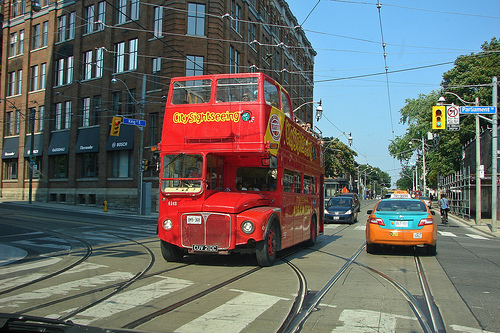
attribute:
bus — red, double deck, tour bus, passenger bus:
[158, 69, 326, 262]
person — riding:
[439, 193, 450, 226]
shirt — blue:
[439, 196, 449, 210]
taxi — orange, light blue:
[366, 198, 437, 252]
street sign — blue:
[459, 105, 497, 115]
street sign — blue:
[120, 115, 149, 129]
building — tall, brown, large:
[1, 1, 159, 214]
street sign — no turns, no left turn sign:
[447, 106, 461, 128]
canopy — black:
[48, 130, 71, 156]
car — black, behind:
[324, 194, 357, 222]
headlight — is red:
[164, 218, 173, 231]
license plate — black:
[193, 244, 219, 252]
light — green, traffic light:
[433, 107, 447, 130]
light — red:
[110, 114, 122, 139]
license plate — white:
[187, 214, 203, 226]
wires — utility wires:
[46, 1, 454, 72]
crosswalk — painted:
[1, 258, 500, 332]